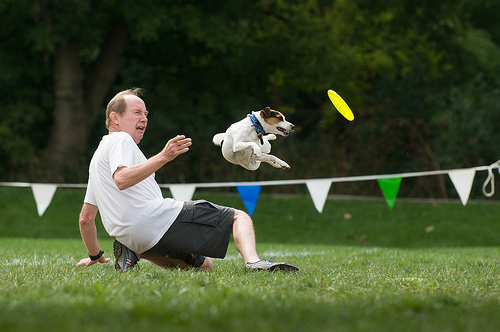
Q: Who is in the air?
A: A dog.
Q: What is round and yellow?
A: Frisbee.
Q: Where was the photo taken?
A: At a park.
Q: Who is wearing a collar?
A: The dog.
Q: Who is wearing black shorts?
A: The man.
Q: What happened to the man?
A: He fell.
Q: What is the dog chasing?
A: Frisbee.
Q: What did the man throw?
A: Frisbee.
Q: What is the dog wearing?
A: Blue collar.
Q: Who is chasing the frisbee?
A: The dog.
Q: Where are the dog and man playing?
A: On a grass field.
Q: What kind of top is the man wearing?
A: White t-shirt.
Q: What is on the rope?
A: Triangle flags.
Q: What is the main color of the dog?
A: White.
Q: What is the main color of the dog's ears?
A: Brown.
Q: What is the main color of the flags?
A: White.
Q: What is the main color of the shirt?
A: White.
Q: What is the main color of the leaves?
A: Green.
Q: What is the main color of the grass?
A: Green.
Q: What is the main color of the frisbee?
A: Yellow.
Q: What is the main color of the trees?
A: Green.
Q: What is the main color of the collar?
A: Blue.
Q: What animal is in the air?
A: A dog.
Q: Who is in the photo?
A: A man and his dog.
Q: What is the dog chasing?
A: A frisbee.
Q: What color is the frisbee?
A: Yellow.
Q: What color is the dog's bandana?
A: Blue.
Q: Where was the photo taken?
A: A park.